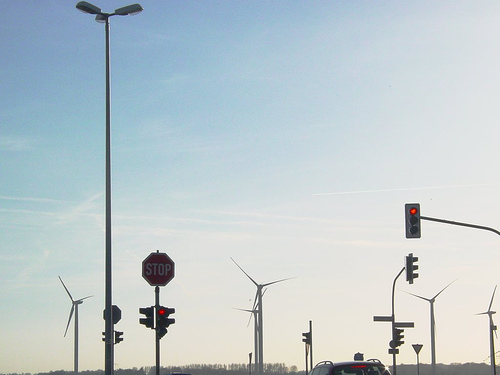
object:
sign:
[141, 253, 173, 286]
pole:
[156, 286, 160, 375]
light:
[157, 308, 166, 316]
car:
[311, 359, 390, 374]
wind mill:
[59, 276, 92, 375]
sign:
[410, 344, 423, 354]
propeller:
[63, 304, 74, 340]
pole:
[104, 24, 113, 375]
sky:
[223, 45, 309, 69]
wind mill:
[232, 259, 286, 375]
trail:
[1, 196, 272, 223]